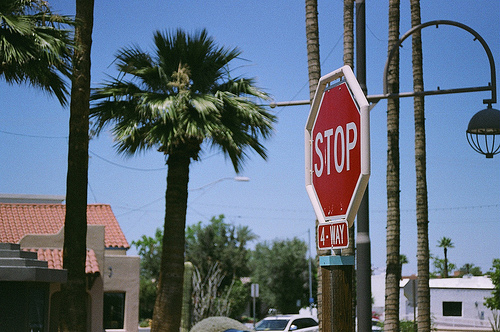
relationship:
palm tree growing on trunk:
[88, 18, 279, 328] [149, 163, 192, 330]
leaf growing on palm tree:
[163, 26, 168, 46] [88, 18, 279, 328]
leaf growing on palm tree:
[240, 80, 247, 94] [88, 18, 279, 328]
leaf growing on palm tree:
[170, 91, 180, 119] [88, 18, 279, 328]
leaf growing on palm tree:
[150, 95, 154, 122] [88, 18, 279, 328]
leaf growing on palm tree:
[240, 134, 269, 161] [88, 18, 279, 328]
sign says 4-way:
[316, 218, 349, 249] [318, 223, 345, 243]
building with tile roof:
[2, 196, 142, 326] [0, 203, 132, 250]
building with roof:
[2, 196, 142, 326] [22, 245, 96, 271]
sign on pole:
[249, 282, 259, 298] [246, 279, 263, 325]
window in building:
[440, 299, 463, 315] [429, 276, 498, 330]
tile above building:
[4, 189, 125, 289] [0, 196, 143, 331]